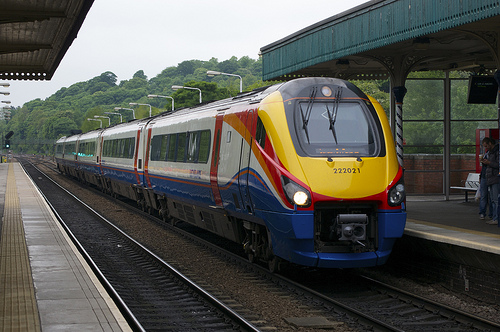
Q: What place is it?
A: It is a station.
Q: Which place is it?
A: It is a station.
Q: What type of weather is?
A: It is clear.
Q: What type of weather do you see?
A: It is clear.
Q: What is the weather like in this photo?
A: It is clear.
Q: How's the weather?
A: It is clear.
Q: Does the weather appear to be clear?
A: Yes, it is clear.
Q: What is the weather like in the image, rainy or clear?
A: It is clear.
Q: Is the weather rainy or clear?
A: It is clear.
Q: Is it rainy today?
A: No, it is clear.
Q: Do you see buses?
A: No, there are no buses.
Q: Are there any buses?
A: No, there are no buses.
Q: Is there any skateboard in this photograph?
A: No, there are no skateboards.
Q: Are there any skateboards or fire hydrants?
A: No, there are no skateboards or fire hydrants.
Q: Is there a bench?
A: Yes, there is a bench.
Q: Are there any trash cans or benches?
A: Yes, there is a bench.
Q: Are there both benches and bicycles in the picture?
A: No, there is a bench but no bicycles.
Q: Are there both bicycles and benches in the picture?
A: No, there is a bench but no bicycles.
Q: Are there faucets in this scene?
A: No, there are no faucets.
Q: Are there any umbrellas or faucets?
A: No, there are no faucets or umbrellas.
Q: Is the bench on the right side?
A: Yes, the bench is on the right of the image.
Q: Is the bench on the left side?
A: No, the bench is on the right of the image.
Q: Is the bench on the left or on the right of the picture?
A: The bench is on the right of the image.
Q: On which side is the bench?
A: The bench is on the right of the image.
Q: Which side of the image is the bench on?
A: The bench is on the right of the image.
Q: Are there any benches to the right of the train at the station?
A: Yes, there is a bench to the right of the train.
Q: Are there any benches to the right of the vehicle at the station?
A: Yes, there is a bench to the right of the train.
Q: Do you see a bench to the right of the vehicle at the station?
A: Yes, there is a bench to the right of the train.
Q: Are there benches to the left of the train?
A: No, the bench is to the right of the train.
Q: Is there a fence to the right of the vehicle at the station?
A: No, there is a bench to the right of the train.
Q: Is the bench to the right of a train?
A: Yes, the bench is to the right of a train.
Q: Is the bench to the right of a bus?
A: No, the bench is to the right of a train.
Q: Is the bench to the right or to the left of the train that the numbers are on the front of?
A: The bench is to the right of the train.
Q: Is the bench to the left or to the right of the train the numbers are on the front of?
A: The bench is to the right of the train.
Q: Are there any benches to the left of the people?
A: Yes, there is a bench to the left of the people.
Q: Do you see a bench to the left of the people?
A: Yes, there is a bench to the left of the people.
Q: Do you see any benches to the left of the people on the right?
A: Yes, there is a bench to the left of the people.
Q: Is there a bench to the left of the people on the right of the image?
A: Yes, there is a bench to the left of the people.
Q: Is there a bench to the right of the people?
A: No, the bench is to the left of the people.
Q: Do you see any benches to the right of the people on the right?
A: No, the bench is to the left of the people.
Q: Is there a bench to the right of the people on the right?
A: No, the bench is to the left of the people.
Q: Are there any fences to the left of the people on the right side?
A: No, there is a bench to the left of the people.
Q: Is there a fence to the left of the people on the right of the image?
A: No, there is a bench to the left of the people.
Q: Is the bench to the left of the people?
A: Yes, the bench is to the left of the people.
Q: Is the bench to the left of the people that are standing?
A: Yes, the bench is to the left of the people.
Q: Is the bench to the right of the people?
A: No, the bench is to the left of the people.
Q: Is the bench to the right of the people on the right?
A: No, the bench is to the left of the people.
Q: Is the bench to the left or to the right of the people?
A: The bench is to the left of the people.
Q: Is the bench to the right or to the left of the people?
A: The bench is to the left of the people.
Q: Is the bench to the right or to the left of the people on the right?
A: The bench is to the left of the people.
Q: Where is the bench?
A: The bench is at the station.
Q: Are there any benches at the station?
A: Yes, there is a bench at the station.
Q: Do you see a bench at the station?
A: Yes, there is a bench at the station.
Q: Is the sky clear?
A: Yes, the sky is clear.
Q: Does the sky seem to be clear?
A: Yes, the sky is clear.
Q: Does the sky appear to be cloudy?
A: No, the sky is clear.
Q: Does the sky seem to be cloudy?
A: No, the sky is clear.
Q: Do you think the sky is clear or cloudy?
A: The sky is clear.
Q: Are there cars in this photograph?
A: No, there are no cars.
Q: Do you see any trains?
A: Yes, there is a train.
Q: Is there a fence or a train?
A: Yes, there is a train.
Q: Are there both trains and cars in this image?
A: No, there is a train but no cars.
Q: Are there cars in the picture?
A: No, there are no cars.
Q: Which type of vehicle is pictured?
A: The vehicle is a train.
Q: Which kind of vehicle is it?
A: The vehicle is a train.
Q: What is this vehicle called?
A: That is a train.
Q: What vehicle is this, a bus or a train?
A: That is a train.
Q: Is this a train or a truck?
A: This is a train.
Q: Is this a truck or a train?
A: This is a train.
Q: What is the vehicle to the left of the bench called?
A: The vehicle is a train.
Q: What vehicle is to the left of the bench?
A: The vehicle is a train.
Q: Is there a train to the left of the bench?
A: Yes, there is a train to the left of the bench.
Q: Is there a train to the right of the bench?
A: No, the train is to the left of the bench.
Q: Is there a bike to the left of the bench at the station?
A: No, there is a train to the left of the bench.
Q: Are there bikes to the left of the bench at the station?
A: No, there is a train to the left of the bench.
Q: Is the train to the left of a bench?
A: Yes, the train is to the left of a bench.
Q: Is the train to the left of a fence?
A: No, the train is to the left of a bench.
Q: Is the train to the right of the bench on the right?
A: No, the train is to the left of the bench.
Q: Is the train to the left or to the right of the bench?
A: The train is to the left of the bench.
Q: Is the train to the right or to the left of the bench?
A: The train is to the left of the bench.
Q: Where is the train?
A: The train is at the station.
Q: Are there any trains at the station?
A: Yes, there is a train at the station.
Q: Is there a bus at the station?
A: No, there is a train at the station.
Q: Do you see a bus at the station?
A: No, there is a train at the station.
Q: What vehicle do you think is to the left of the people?
A: The vehicle is a train.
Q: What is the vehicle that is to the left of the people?
A: The vehicle is a train.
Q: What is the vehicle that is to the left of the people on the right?
A: The vehicle is a train.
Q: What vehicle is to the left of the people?
A: The vehicle is a train.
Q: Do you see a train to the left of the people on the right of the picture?
A: Yes, there is a train to the left of the people.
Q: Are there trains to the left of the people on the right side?
A: Yes, there is a train to the left of the people.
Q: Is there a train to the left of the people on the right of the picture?
A: Yes, there is a train to the left of the people.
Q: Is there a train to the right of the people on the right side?
A: No, the train is to the left of the people.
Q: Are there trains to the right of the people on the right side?
A: No, the train is to the left of the people.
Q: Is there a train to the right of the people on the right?
A: No, the train is to the left of the people.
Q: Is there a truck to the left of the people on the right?
A: No, there is a train to the left of the people.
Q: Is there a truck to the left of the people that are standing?
A: No, there is a train to the left of the people.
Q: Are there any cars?
A: No, there are no cars.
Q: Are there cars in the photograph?
A: No, there are no cars.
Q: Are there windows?
A: Yes, there are windows.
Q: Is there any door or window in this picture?
A: Yes, there are windows.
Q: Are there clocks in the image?
A: No, there are no clocks.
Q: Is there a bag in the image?
A: No, there are no bags.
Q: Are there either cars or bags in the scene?
A: No, there are no bags or cars.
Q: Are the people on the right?
A: Yes, the people are on the right of the image.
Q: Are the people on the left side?
A: No, the people are on the right of the image.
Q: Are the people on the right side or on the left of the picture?
A: The people are on the right of the image.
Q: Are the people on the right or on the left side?
A: The people are on the right of the image.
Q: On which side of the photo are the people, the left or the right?
A: The people are on the right of the image.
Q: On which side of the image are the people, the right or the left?
A: The people are on the right of the image.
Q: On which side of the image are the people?
A: The people are on the right of the image.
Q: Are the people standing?
A: Yes, the people are standing.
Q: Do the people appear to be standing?
A: Yes, the people are standing.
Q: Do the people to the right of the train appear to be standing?
A: Yes, the people are standing.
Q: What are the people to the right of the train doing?
A: The people are standing.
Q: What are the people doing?
A: The people are standing.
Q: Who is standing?
A: The people are standing.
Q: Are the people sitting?
A: No, the people are standing.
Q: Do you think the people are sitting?
A: No, the people are standing.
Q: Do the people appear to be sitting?
A: No, the people are standing.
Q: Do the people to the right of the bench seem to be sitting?
A: No, the people are standing.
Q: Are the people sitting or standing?
A: The people are standing.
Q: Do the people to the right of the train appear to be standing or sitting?
A: The people are standing.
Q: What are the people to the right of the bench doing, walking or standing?
A: The people are standing.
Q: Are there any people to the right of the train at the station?
A: Yes, there are people to the right of the train.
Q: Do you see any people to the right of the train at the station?
A: Yes, there are people to the right of the train.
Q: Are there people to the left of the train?
A: No, the people are to the right of the train.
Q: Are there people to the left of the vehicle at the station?
A: No, the people are to the right of the train.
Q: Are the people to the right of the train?
A: Yes, the people are to the right of the train.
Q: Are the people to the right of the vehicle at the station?
A: Yes, the people are to the right of the train.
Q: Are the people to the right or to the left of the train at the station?
A: The people are to the right of the train.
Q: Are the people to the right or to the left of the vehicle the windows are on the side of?
A: The people are to the right of the train.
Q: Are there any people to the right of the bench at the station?
A: Yes, there are people to the right of the bench.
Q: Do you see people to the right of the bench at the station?
A: Yes, there are people to the right of the bench.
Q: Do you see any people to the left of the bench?
A: No, the people are to the right of the bench.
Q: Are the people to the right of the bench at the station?
A: Yes, the people are to the right of the bench.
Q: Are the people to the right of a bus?
A: No, the people are to the right of the bench.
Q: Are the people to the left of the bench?
A: No, the people are to the right of the bench.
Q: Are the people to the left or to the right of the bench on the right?
A: The people are to the right of the bench.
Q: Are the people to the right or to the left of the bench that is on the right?
A: The people are to the right of the bench.